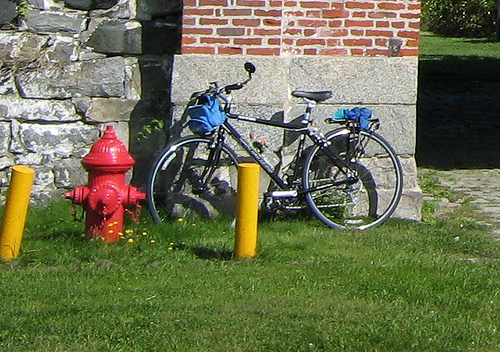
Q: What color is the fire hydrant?
A: Red.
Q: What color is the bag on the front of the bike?
A: Blue.